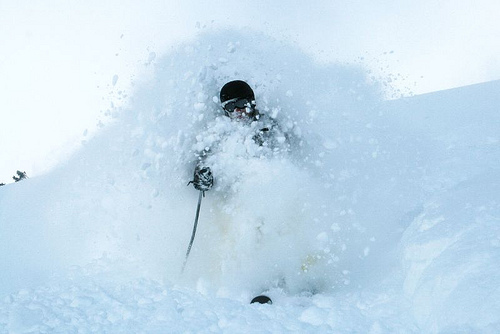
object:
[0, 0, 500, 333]
outside scene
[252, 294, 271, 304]
ski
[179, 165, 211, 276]
pole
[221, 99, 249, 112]
goggles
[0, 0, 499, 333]
snow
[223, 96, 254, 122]
snow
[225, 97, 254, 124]
person face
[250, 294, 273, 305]
tip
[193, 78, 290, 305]
person